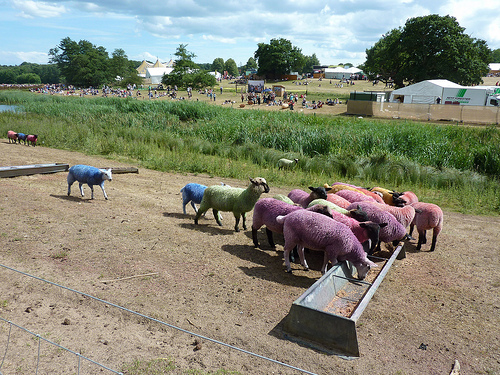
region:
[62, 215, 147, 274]
dirt on the ground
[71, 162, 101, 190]
sheep with blue wool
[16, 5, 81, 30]
clouds in the sky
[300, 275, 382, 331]
part of the feeding trough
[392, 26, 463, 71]
leaves on the tree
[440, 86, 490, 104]
a green and white truck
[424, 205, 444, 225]
rear end of sheep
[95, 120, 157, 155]
area of green grass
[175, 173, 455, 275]
group of the sheep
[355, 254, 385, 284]
head of a sheep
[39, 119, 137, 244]
the sheep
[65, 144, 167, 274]
the zebra has stripes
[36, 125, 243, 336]
the zebra has stripes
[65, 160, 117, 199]
A blue sheep with a white head.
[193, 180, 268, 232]
A green sheep.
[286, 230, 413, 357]
A metal food trough.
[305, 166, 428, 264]
A group of sheep eating.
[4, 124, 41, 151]
Three sheep walking in a row.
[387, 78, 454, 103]
A white tent.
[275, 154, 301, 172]
A sheep walking in the grass.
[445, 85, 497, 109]
A white and green truck.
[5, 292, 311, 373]
A metal fence.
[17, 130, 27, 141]
A blue sheep between pink sheep.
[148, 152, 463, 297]
Sheep have colored wool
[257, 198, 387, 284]
Sheep eating out of trough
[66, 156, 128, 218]
Lamb is blue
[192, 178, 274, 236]
Green sheep towards back of pack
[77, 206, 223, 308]
Grass is dead only dirt left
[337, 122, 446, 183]
Tall grassy field in background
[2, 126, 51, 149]
Three colored sheep walking in a line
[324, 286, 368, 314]
Grain inside the trough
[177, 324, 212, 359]
Rocks laying in the dirt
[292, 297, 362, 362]
The trough is made of metal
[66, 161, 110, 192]
blue colored sheep wool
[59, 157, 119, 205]
blue colored sheep wool